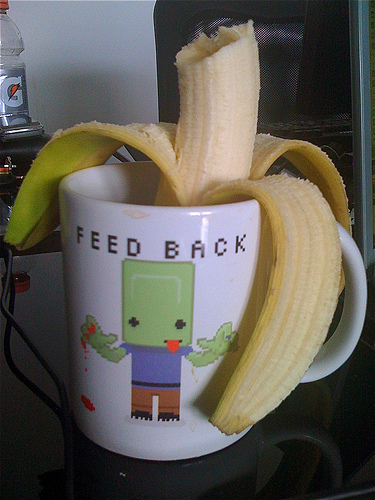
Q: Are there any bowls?
A: No, there are no bowls.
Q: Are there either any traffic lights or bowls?
A: No, there are no bowls or traffic lights.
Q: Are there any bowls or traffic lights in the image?
A: No, there are no bowls or traffic lights.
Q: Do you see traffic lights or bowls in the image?
A: No, there are no bowls or traffic lights.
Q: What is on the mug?
A: The figure is on the mug.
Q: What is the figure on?
A: The figure is on the mug.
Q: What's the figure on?
A: The figure is on the mug.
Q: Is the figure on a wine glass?
A: No, the figure is on the mug.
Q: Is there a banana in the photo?
A: Yes, there is a banana.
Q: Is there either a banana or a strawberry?
A: Yes, there is a banana.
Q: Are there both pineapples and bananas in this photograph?
A: No, there is a banana but no pineapples.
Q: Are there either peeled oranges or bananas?
A: Yes, there is a peeled banana.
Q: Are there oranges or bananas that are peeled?
A: Yes, the banana is peeled.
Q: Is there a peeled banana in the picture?
A: Yes, there is a peeled banana.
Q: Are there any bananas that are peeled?
A: Yes, there is a banana that is peeled.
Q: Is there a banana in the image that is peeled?
A: Yes, there is a banana that is peeled.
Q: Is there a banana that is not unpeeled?
A: Yes, there is an peeled banana.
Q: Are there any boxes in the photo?
A: No, there are no boxes.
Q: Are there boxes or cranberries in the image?
A: No, there are no boxes or cranberries.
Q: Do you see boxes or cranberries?
A: No, there are no boxes or cranberries.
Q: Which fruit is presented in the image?
A: The fruit is a banana.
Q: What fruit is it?
A: The fruit is a banana.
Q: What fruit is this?
A: That is a banana.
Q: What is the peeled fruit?
A: The fruit is a banana.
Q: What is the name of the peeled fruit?
A: The fruit is a banana.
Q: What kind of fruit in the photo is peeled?
A: The fruit is a banana.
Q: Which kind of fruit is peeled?
A: The fruit is a banana.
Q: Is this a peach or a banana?
A: This is a banana.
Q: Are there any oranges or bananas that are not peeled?
A: No, there is a banana but it is peeled.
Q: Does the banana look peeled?
A: Yes, the banana is peeled.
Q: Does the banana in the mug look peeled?
A: Yes, the banana is peeled.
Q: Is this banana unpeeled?
A: No, the banana is peeled.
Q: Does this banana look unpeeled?
A: No, the banana is peeled.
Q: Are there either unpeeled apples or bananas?
A: No, there is a banana but it is peeled.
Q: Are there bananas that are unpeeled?
A: No, there is a banana but it is peeled.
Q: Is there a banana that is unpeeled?
A: No, there is a banana but it is peeled.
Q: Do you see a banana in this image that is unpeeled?
A: No, there is a banana but it is peeled.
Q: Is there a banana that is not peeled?
A: No, there is a banana but it is peeled.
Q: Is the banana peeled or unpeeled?
A: The banana is peeled.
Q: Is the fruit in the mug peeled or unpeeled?
A: The banana is peeled.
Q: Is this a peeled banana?
A: Yes, this is a peeled banana.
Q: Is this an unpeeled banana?
A: No, this is a peeled banana.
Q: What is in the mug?
A: The banana is in the mug.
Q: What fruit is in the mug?
A: The fruit is a banana.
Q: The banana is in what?
A: The banana is in the mug.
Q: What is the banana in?
A: The banana is in the mug.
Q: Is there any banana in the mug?
A: Yes, there is a banana in the mug.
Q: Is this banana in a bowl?
A: No, the banana is in the mug.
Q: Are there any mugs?
A: Yes, there is a mug.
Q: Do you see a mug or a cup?
A: Yes, there is a mug.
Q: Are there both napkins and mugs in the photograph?
A: No, there is a mug but no napkins.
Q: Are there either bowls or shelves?
A: No, there are no bowls or shelves.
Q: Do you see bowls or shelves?
A: No, there are no bowls or shelves.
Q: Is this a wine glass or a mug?
A: This is a mug.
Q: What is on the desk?
A: The mug is on the desk.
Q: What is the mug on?
A: The mug is on the desk.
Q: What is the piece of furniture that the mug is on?
A: The piece of furniture is a desk.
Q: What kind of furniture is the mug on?
A: The mug is on the desk.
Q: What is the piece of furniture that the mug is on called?
A: The piece of furniture is a desk.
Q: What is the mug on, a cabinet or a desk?
A: The mug is on a desk.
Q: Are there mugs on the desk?
A: Yes, there is a mug on the desk.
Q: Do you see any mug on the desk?
A: Yes, there is a mug on the desk.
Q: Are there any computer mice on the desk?
A: No, there is a mug on the desk.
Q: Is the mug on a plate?
A: No, the mug is on the desk.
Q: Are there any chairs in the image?
A: Yes, there is a chair.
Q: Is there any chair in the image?
A: Yes, there is a chair.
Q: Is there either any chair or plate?
A: Yes, there is a chair.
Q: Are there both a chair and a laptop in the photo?
A: No, there is a chair but no laptops.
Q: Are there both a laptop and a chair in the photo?
A: No, there is a chair but no laptops.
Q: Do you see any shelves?
A: No, there are no shelves.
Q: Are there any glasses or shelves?
A: No, there are no shelves or glasses.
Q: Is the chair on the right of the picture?
A: Yes, the chair is on the right of the image.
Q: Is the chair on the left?
A: No, the chair is on the right of the image.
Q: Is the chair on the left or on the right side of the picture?
A: The chair is on the right of the image.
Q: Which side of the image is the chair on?
A: The chair is on the right of the image.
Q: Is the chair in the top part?
A: Yes, the chair is in the top of the image.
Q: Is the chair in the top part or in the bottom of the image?
A: The chair is in the top of the image.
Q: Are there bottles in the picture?
A: Yes, there is a bottle.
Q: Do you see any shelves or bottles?
A: Yes, there is a bottle.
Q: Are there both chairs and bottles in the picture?
A: Yes, there are both a bottle and a chair.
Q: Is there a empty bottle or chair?
A: Yes, there is an empty bottle.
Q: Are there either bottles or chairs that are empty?
A: Yes, the bottle is empty.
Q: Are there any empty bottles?
A: Yes, there is an empty bottle.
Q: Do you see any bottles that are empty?
A: Yes, there is a bottle that is empty.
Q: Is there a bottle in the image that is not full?
A: Yes, there is a empty bottle.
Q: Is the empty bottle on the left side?
A: Yes, the bottle is on the left of the image.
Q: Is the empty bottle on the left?
A: Yes, the bottle is on the left of the image.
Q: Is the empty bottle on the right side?
A: No, the bottle is on the left of the image.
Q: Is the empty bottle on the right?
A: No, the bottle is on the left of the image.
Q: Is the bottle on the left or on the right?
A: The bottle is on the left of the image.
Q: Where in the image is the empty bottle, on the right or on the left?
A: The bottle is on the left of the image.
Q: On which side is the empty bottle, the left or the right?
A: The bottle is on the left of the image.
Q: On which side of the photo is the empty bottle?
A: The bottle is on the left of the image.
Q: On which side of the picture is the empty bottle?
A: The bottle is on the left of the image.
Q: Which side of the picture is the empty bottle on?
A: The bottle is on the left of the image.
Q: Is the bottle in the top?
A: Yes, the bottle is in the top of the image.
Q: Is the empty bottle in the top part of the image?
A: Yes, the bottle is in the top of the image.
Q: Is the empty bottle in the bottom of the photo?
A: No, the bottle is in the top of the image.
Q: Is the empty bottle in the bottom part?
A: No, the bottle is in the top of the image.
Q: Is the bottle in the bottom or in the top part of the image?
A: The bottle is in the top of the image.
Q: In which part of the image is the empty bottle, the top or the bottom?
A: The bottle is in the top of the image.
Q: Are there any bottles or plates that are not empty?
A: No, there is a bottle but it is empty.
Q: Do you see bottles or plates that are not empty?
A: No, there is a bottle but it is empty.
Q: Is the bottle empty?
A: Yes, the bottle is empty.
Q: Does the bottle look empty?
A: Yes, the bottle is empty.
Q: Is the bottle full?
A: No, the bottle is empty.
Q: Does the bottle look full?
A: No, the bottle is empty.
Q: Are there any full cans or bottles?
A: No, there is a bottle but it is empty.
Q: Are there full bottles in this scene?
A: No, there is a bottle but it is empty.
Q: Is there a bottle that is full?
A: No, there is a bottle but it is empty.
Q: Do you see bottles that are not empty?
A: No, there is a bottle but it is empty.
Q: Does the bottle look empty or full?
A: The bottle is empty.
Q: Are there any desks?
A: Yes, there is a desk.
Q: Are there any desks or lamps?
A: Yes, there is a desk.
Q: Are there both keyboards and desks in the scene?
A: No, there is a desk but no keyboards.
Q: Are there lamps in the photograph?
A: No, there are no lamps.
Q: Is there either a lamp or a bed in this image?
A: No, there are no lamps or beds.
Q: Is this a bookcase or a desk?
A: This is a desk.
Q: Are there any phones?
A: Yes, there is a phone.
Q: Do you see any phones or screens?
A: Yes, there is a phone.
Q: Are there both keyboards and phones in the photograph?
A: No, there is a phone but no keyboards.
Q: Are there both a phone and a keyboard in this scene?
A: No, there is a phone but no keyboards.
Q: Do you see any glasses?
A: No, there are no glasses.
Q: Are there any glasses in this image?
A: No, there are no glasses.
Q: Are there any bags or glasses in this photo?
A: No, there are no glasses or bags.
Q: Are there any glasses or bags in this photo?
A: No, there are no glasses or bags.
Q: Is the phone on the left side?
A: Yes, the phone is on the left of the image.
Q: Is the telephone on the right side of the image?
A: No, the telephone is on the left of the image.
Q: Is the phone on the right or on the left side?
A: The phone is on the left of the image.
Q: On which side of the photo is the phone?
A: The phone is on the left of the image.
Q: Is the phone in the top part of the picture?
A: Yes, the phone is in the top of the image.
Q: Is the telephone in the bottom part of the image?
A: No, the telephone is in the top of the image.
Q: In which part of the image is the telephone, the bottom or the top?
A: The telephone is in the top of the image.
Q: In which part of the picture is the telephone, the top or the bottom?
A: The telephone is in the top of the image.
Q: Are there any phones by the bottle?
A: Yes, there is a phone by the bottle.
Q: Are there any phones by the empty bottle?
A: Yes, there is a phone by the bottle.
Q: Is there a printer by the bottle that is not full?
A: No, there is a phone by the bottle.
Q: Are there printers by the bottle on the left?
A: No, there is a phone by the bottle.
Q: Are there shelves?
A: No, there are no shelves.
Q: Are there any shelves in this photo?
A: No, there are no shelves.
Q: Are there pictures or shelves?
A: No, there are no shelves or pictures.